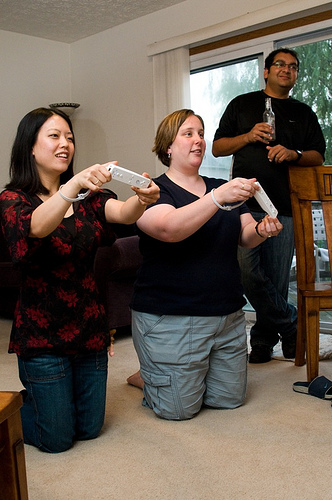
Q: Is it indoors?
A: Yes, it is indoors.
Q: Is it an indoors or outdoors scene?
A: It is indoors.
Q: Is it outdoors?
A: No, it is indoors.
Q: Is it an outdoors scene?
A: No, it is indoors.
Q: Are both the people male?
A: No, they are both male and female.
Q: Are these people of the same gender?
A: No, they are both male and female.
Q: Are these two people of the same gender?
A: No, they are both male and female.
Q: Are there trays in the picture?
A: No, there are no trays.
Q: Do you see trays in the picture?
A: No, there are no trays.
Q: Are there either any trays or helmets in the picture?
A: No, there are no trays or helmets.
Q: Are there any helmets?
A: No, there are no helmets.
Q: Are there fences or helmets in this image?
A: No, there are no helmets or fences.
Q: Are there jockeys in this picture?
A: No, there are no jockeys.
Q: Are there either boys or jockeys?
A: No, there are no jockeys or boys.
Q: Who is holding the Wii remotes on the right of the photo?
A: The lady is holding the Wii remotes.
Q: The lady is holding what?
A: The lady is holding the Wii controller.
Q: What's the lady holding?
A: The lady is holding the Wii controller.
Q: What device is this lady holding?
A: The lady is holding the Wii remotes.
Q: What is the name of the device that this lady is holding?
A: The device is a Wii controller.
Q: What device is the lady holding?
A: The lady is holding the Wii remotes.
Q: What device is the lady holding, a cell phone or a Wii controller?
A: The lady is holding a Wii controller.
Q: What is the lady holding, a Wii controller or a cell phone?
A: The lady is holding a Wii controller.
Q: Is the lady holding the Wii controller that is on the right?
A: Yes, the lady is holding the Wii controller.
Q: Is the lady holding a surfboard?
A: No, the lady is holding the Wii controller.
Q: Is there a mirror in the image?
A: No, there are no mirrors.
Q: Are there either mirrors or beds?
A: No, there are no mirrors or beds.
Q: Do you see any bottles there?
A: Yes, there is a bottle.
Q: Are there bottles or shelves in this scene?
A: Yes, there is a bottle.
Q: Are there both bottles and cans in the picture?
A: No, there is a bottle but no cans.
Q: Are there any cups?
A: No, there are no cups.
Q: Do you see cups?
A: No, there are no cups.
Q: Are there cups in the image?
A: No, there are no cups.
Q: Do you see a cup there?
A: No, there are no cups.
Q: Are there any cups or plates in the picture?
A: No, there are no cups or plates.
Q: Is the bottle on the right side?
A: Yes, the bottle is on the right of the image.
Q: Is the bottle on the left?
A: No, the bottle is on the right of the image.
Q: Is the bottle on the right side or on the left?
A: The bottle is on the right of the image.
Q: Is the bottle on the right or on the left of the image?
A: The bottle is on the right of the image.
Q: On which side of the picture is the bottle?
A: The bottle is on the right of the image.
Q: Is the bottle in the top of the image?
A: Yes, the bottle is in the top of the image.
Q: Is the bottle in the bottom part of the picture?
A: No, the bottle is in the top of the image.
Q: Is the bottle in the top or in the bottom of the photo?
A: The bottle is in the top of the image.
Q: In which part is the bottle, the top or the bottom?
A: The bottle is in the top of the image.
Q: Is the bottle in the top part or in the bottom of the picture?
A: The bottle is in the top of the image.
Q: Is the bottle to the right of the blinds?
A: Yes, the bottle is to the right of the blinds.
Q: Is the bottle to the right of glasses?
A: No, the bottle is to the right of the blinds.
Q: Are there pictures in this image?
A: No, there are no pictures.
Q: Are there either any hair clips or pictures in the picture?
A: No, there are no pictures or hair clips.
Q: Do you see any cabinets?
A: No, there are no cabinets.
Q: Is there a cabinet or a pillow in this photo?
A: No, there are no cabinets or pillows.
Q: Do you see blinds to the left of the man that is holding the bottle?
A: Yes, there are blinds to the left of the man.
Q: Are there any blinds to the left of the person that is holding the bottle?
A: Yes, there are blinds to the left of the man.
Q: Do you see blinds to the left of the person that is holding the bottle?
A: Yes, there are blinds to the left of the man.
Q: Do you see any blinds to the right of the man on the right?
A: No, the blinds are to the left of the man.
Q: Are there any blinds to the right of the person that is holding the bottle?
A: No, the blinds are to the left of the man.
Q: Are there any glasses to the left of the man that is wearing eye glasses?
A: No, there are blinds to the left of the man.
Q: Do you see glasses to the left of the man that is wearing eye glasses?
A: No, there are blinds to the left of the man.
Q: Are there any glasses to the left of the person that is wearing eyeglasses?
A: No, there are blinds to the left of the man.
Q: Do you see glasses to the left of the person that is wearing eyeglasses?
A: No, there are blinds to the left of the man.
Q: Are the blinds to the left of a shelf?
A: No, the blinds are to the left of a man.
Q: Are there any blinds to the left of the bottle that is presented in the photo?
A: Yes, there are blinds to the left of the bottle.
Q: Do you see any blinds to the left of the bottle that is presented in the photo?
A: Yes, there are blinds to the left of the bottle.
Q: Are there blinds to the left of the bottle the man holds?
A: Yes, there are blinds to the left of the bottle.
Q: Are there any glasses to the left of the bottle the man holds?
A: No, there are blinds to the left of the bottle.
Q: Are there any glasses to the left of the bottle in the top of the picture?
A: No, there are blinds to the left of the bottle.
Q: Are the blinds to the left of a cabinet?
A: No, the blinds are to the left of a bottle.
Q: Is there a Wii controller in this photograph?
A: Yes, there is a Wii controller.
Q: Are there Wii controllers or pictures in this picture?
A: Yes, there is a Wii controller.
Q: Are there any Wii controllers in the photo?
A: Yes, there is a Wii controller.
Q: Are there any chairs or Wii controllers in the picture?
A: Yes, there is a Wii controller.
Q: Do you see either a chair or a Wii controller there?
A: Yes, there is a Wii controller.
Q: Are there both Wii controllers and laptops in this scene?
A: No, there is a Wii controller but no laptops.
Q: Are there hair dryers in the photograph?
A: No, there are no hair dryers.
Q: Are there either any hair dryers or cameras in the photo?
A: No, there are no hair dryers or cameras.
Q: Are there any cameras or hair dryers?
A: No, there are no hair dryers or cameras.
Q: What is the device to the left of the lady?
A: The device is a Wii controller.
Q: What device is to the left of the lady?
A: The device is a Wii controller.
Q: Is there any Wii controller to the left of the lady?
A: Yes, there is a Wii controller to the left of the lady.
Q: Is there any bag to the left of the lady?
A: No, there is a Wii controller to the left of the lady.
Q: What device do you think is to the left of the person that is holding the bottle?
A: The device is a Wii controller.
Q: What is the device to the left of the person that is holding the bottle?
A: The device is a Wii controller.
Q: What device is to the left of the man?
A: The device is a Wii controller.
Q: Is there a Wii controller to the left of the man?
A: Yes, there is a Wii controller to the left of the man.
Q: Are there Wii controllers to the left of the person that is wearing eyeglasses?
A: Yes, there is a Wii controller to the left of the man.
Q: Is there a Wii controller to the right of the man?
A: No, the Wii controller is to the left of the man.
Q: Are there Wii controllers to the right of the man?
A: No, the Wii controller is to the left of the man.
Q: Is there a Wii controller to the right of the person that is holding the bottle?
A: No, the Wii controller is to the left of the man.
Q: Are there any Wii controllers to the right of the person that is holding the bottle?
A: No, the Wii controller is to the left of the man.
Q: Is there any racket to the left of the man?
A: No, there is a Wii controller to the left of the man.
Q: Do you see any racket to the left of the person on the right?
A: No, there is a Wii controller to the left of the man.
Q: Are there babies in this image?
A: No, there are no babies.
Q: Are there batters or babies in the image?
A: No, there are no babies or batters.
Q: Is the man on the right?
A: Yes, the man is on the right of the image.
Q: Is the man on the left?
A: No, the man is on the right of the image.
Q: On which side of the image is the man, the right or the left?
A: The man is on the right of the image.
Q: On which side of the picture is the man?
A: The man is on the right of the image.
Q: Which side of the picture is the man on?
A: The man is on the right of the image.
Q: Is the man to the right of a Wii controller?
A: Yes, the man is to the right of a Wii controller.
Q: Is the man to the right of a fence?
A: No, the man is to the right of a Wii controller.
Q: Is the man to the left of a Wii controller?
A: No, the man is to the right of a Wii controller.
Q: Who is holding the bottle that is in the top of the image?
A: The man is holding the bottle.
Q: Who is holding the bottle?
A: The man is holding the bottle.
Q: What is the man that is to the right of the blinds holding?
A: The man is holding the bottle.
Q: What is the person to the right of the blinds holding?
A: The man is holding the bottle.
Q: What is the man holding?
A: The man is holding the bottle.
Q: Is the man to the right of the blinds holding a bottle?
A: Yes, the man is holding a bottle.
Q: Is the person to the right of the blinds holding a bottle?
A: Yes, the man is holding a bottle.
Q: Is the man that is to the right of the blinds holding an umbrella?
A: No, the man is holding a bottle.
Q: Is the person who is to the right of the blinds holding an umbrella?
A: No, the man is holding a bottle.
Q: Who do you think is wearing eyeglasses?
A: The man is wearing eyeglasses.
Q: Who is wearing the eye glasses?
A: The man is wearing eyeglasses.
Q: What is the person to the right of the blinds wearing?
A: The man is wearing eyeglasses.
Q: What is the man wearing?
A: The man is wearing eyeglasses.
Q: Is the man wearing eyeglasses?
A: Yes, the man is wearing eyeglasses.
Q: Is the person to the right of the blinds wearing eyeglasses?
A: Yes, the man is wearing eyeglasses.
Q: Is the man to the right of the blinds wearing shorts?
A: No, the man is wearing eyeglasses.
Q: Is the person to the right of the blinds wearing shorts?
A: No, the man is wearing eyeglasses.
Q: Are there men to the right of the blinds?
A: Yes, there is a man to the right of the blinds.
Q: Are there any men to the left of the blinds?
A: No, the man is to the right of the blinds.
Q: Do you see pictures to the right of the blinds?
A: No, there is a man to the right of the blinds.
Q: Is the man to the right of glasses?
A: No, the man is to the right of the blinds.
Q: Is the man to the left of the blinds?
A: No, the man is to the right of the blinds.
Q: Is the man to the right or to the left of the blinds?
A: The man is to the right of the blinds.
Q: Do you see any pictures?
A: No, there are no pictures.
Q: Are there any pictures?
A: No, there are no pictures.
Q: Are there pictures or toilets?
A: No, there are no pictures or toilets.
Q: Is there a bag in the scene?
A: No, there are no bags.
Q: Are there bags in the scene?
A: No, there are no bags.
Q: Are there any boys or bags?
A: No, there are no bags or boys.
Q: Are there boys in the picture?
A: No, there are no boys.